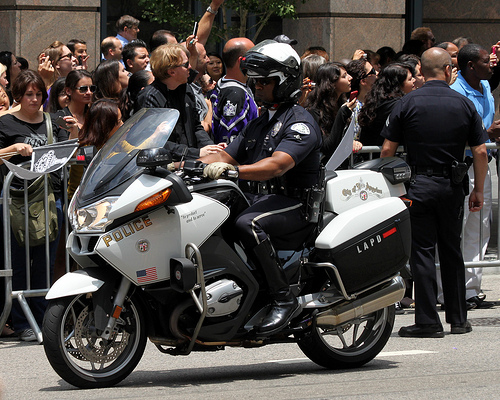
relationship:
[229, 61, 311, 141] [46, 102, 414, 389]
officer on bike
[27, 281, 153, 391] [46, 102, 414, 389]
tire of bike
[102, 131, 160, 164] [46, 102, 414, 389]
windshield of bike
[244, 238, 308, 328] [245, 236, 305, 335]
knee-high motorcycle black boots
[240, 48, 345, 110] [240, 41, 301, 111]
black and white motorcycle black and white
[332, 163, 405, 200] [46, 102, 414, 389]
cargo box of bike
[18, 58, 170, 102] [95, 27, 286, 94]
crowd of people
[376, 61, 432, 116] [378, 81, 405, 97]
woman wearing black hair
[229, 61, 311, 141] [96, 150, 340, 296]
cop in a bike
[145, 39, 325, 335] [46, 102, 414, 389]
officer riding bike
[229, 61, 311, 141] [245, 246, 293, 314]
officer wearing black boots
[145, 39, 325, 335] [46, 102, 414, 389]
officer standing behind bike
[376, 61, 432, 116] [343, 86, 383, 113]
woman wearing black shirt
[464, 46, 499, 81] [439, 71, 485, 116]
man wearing blue shirt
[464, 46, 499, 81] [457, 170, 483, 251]
man wearing white pants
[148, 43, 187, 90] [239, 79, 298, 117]
man wearing dark sunglasses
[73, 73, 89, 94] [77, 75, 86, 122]
woman wearing dark sunglasses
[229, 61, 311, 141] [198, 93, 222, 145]
officer wearing beige gloves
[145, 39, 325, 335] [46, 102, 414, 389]
officer sitting on bike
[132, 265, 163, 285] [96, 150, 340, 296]
american flag on bike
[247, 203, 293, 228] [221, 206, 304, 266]
white stripe on pants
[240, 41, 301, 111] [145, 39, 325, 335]
black and white on officer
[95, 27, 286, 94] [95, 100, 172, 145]
people on road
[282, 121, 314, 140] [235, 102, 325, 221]
patch on uniform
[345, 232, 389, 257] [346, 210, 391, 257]
white letters on black case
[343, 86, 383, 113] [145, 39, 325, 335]
black shirt on officer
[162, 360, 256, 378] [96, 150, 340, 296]
shadow of bike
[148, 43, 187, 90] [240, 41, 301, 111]
man has black and white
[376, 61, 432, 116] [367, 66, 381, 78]
woman has sun glasses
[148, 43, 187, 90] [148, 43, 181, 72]
man with hair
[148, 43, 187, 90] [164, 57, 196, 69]
man wearing sunglasses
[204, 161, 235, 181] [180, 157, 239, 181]
beige gloves on handlebar